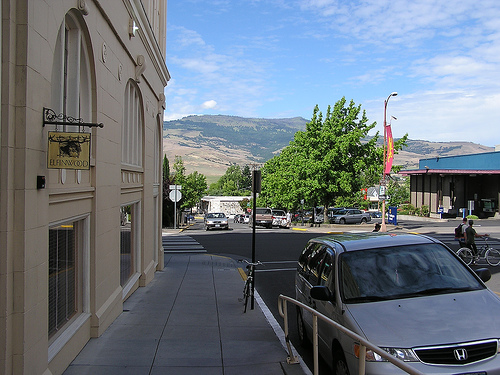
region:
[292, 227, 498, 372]
a silver car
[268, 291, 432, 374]
a railing next to the road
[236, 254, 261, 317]
a bicycle leaning on a sign post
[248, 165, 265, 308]
a sign post next to the road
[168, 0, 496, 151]
a blue and white cloudy sky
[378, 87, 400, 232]
a lamp post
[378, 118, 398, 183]
a red banner hanging from a light post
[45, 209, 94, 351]
a window in a building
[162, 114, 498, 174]
a mountain in the distance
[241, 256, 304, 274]
the white lines of a crosswalk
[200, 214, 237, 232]
car stopped at intersection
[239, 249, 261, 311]
bike chained next to a pole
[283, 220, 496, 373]
vehicle parked along sidewalk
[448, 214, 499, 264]
two people next to a bike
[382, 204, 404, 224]
blue mail box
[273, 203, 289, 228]
white vehicle parked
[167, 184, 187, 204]
back of stop sign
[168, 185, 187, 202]
hexagon shaped sign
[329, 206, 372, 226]
car parked in parking lot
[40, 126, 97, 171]
yellow sign with black print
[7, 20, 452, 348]
This is on a city street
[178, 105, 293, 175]
There are mountains in the background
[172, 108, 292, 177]
The mountain is green and brown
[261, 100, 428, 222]
These are trees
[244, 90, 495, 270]
The tree leaves are green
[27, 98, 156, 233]
The sign is yellow and black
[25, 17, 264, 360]
The building is tan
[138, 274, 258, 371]
The sidewalk is gray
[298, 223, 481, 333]
The car is silver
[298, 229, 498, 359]
This is a vehicle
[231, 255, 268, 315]
a bike leaning against a pole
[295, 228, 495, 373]
a car parked by the metal rail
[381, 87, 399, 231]
a lightpost with a banner hanging from it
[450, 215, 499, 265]
two people walking a bike across the street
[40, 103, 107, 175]
an ornate sign hanging from the building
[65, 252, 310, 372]
a sidewalk next to the building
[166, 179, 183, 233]
the back of a distant stop sign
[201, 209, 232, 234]
a car on the street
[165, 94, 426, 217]
trees and bushes across the street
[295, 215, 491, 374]
a car parked in the parking area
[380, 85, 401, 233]
a lamp with its post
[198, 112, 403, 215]
mountain with trees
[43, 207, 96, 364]
window of the building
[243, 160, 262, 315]
advertisement post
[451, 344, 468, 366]
brand symbol of the car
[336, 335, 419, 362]
headlight with indicator of the car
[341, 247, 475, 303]
front glass of the car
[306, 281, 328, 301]
side mirror of the car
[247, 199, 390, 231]
many cars parked under the tree